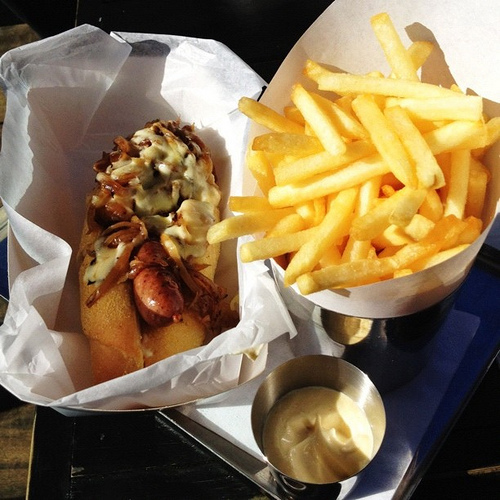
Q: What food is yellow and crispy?
A: French fries.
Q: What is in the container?
A: Sauce.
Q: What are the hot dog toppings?
A: Cheese and onions.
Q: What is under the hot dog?
A: Wax paper.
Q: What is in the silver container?
A: Mayonnaise.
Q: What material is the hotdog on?
A: Wax Paper.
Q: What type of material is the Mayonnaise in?
A: Silver Metal.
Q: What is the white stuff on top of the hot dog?
A: Cheese.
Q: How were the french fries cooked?
A: In Oil.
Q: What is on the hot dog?
A: Sauteed onions and cheese.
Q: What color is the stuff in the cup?
A: White.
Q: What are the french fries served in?
A: Metal tin with paper.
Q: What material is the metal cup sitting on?
A: White Napkin.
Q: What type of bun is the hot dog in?
A: White hot dog bun.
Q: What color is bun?
A: White.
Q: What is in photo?
A: Hotdog and fries.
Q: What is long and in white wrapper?
A: French fries.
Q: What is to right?
A: French fries.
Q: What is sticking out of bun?
A: Frankfurter.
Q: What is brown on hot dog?
A: Fried brown onions.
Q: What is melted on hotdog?
A: Cheese.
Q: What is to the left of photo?
A: Hot dog in paper wrapper.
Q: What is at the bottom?
A: Metal container with dipping sauce.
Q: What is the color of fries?
A: Yellow.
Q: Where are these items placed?
A: On tray.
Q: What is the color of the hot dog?
A: Brown.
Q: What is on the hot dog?
A: Cheese.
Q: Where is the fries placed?
A: In the metal bowl.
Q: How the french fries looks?
A: So yummy.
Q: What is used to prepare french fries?
A: Potato.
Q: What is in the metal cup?
A: Mayonnaise.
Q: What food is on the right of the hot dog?
A: French Fries.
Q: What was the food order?
A: A hotdog, french fries and mayonnaise.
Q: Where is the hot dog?
A: The hot dog is sitting in the split of the hot dog bun.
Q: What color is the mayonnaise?
A: Cream.